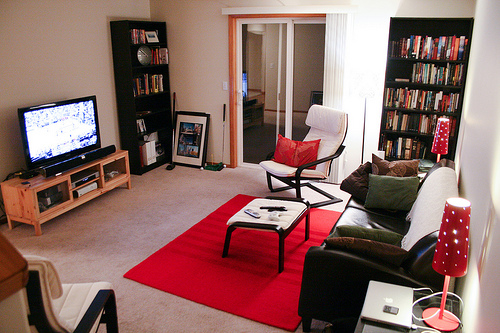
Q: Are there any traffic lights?
A: No, there are no traffic lights.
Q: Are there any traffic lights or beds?
A: No, there are no traffic lights or beds.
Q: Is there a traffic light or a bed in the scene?
A: No, there are no traffic lights or beds.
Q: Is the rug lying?
A: Yes, the rug is lying.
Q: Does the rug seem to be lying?
A: Yes, the rug is lying.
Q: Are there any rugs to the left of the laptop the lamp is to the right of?
A: Yes, there is a rug to the left of the laptop computer.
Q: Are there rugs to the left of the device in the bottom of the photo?
A: Yes, there is a rug to the left of the laptop computer.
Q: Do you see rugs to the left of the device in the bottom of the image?
A: Yes, there is a rug to the left of the laptop computer.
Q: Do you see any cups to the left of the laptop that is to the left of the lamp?
A: No, there is a rug to the left of the laptop.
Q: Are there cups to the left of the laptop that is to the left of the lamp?
A: No, there is a rug to the left of the laptop.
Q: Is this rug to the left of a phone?
A: No, the rug is to the left of the laptop.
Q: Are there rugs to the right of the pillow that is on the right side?
A: No, the rug is to the left of the pillow.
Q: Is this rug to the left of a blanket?
A: No, the rug is to the left of the pillow.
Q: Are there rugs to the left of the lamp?
A: Yes, there is a rug to the left of the lamp.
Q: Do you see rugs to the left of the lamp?
A: Yes, there is a rug to the left of the lamp.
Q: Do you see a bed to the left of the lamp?
A: No, there is a rug to the left of the lamp.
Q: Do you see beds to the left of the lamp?
A: No, there is a rug to the left of the lamp.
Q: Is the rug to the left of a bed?
A: No, the rug is to the left of a lamp.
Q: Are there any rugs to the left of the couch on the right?
A: Yes, there is a rug to the left of the couch.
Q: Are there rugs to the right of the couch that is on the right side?
A: No, the rug is to the left of the couch.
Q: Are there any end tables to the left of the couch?
A: No, there is a rug to the left of the couch.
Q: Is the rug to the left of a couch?
A: Yes, the rug is to the left of a couch.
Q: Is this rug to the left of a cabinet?
A: No, the rug is to the left of a couch.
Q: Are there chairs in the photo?
A: Yes, there is a chair.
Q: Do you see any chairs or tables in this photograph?
A: Yes, there is a chair.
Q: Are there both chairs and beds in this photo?
A: No, there is a chair but no beds.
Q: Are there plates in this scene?
A: No, there are no plates.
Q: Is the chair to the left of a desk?
A: No, the chair is to the left of a pillow.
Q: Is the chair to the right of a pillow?
A: No, the chair is to the left of a pillow.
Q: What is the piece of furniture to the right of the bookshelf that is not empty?
A: The piece of furniture is a chair.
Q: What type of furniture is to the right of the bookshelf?
A: The piece of furniture is a chair.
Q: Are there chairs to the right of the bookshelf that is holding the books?
A: Yes, there is a chair to the right of the bookshelf.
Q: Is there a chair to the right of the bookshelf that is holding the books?
A: Yes, there is a chair to the right of the bookshelf.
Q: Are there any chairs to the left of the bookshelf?
A: No, the chair is to the right of the bookshelf.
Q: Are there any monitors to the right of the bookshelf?
A: No, there is a chair to the right of the bookshelf.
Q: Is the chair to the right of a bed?
A: No, the chair is to the right of the bookshelf.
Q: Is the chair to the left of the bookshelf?
A: No, the chair is to the right of the bookshelf.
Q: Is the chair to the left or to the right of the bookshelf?
A: The chair is to the right of the bookshelf.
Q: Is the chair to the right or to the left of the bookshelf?
A: The chair is to the right of the bookshelf.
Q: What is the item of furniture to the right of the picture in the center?
A: The piece of furniture is a chair.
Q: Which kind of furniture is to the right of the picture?
A: The piece of furniture is a chair.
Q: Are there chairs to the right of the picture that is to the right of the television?
A: Yes, there is a chair to the right of the picture.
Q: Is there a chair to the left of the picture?
A: No, the chair is to the right of the picture.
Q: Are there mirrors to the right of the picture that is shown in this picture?
A: No, there is a chair to the right of the picture.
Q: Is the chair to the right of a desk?
A: No, the chair is to the right of the picture.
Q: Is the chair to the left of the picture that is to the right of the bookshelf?
A: No, the chair is to the right of the picture.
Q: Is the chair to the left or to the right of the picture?
A: The chair is to the right of the picture.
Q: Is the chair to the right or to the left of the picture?
A: The chair is to the right of the picture.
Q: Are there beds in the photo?
A: No, there are no beds.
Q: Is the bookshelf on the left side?
A: Yes, the bookshelf is on the left of the image.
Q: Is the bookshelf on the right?
A: No, the bookshelf is on the left of the image.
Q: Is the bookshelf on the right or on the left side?
A: The bookshelf is on the left of the image.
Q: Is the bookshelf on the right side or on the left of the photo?
A: The bookshelf is on the left of the image.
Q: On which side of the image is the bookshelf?
A: The bookshelf is on the left of the image.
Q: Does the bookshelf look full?
A: Yes, the bookshelf is full.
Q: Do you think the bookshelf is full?
A: Yes, the bookshelf is full.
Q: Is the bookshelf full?
A: Yes, the bookshelf is full.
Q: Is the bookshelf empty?
A: No, the bookshelf is full.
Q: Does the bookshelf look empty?
A: No, the bookshelf is full.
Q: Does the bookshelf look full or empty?
A: The bookshelf is full.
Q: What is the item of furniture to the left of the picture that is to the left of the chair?
A: The piece of furniture is a bookshelf.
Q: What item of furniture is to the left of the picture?
A: The piece of furniture is a bookshelf.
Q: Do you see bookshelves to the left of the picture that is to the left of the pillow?
A: Yes, there is a bookshelf to the left of the picture.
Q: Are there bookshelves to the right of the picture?
A: No, the bookshelf is to the left of the picture.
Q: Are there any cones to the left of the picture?
A: No, there is a bookshelf to the left of the picture.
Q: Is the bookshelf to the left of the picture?
A: Yes, the bookshelf is to the left of the picture.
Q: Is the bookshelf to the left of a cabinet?
A: No, the bookshelf is to the left of the picture.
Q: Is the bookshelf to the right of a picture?
A: No, the bookshelf is to the left of a picture.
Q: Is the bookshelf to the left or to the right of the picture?
A: The bookshelf is to the left of the picture.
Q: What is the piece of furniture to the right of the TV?
A: The piece of furniture is a bookshelf.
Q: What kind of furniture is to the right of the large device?
A: The piece of furniture is a bookshelf.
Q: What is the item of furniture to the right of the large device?
A: The piece of furniture is a bookshelf.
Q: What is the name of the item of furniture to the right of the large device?
A: The piece of furniture is a bookshelf.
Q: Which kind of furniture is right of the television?
A: The piece of furniture is a bookshelf.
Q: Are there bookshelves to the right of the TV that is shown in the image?
A: Yes, there is a bookshelf to the right of the TV.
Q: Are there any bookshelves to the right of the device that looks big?
A: Yes, there is a bookshelf to the right of the TV.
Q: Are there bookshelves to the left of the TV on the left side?
A: No, the bookshelf is to the right of the TV.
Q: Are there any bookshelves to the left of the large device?
A: No, the bookshelf is to the right of the TV.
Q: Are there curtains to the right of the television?
A: No, there is a bookshelf to the right of the television.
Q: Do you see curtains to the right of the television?
A: No, there is a bookshelf to the right of the television.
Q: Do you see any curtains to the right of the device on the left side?
A: No, there is a bookshelf to the right of the television.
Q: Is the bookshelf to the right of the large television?
A: Yes, the bookshelf is to the right of the television.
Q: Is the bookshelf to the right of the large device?
A: Yes, the bookshelf is to the right of the television.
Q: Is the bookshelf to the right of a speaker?
A: No, the bookshelf is to the right of the television.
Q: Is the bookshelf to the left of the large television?
A: No, the bookshelf is to the right of the television.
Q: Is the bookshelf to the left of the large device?
A: No, the bookshelf is to the right of the television.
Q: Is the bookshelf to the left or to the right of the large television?
A: The bookshelf is to the right of the television.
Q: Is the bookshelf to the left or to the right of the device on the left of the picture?
A: The bookshelf is to the right of the television.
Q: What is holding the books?
A: The bookshelf is holding the books.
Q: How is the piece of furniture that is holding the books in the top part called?
A: The piece of furniture is a bookshelf.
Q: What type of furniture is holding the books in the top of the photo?
A: The piece of furniture is a bookshelf.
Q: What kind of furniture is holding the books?
A: The piece of furniture is a bookshelf.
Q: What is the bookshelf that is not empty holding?
A: The bookshelf is holding the books.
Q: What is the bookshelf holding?
A: The bookshelf is holding the books.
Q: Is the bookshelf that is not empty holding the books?
A: Yes, the bookshelf is holding the books.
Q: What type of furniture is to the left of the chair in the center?
A: The piece of furniture is a bookshelf.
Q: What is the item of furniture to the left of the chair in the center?
A: The piece of furniture is a bookshelf.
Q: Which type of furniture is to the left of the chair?
A: The piece of furniture is a bookshelf.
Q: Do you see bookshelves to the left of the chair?
A: Yes, there is a bookshelf to the left of the chair.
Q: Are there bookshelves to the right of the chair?
A: No, the bookshelf is to the left of the chair.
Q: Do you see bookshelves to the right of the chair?
A: No, the bookshelf is to the left of the chair.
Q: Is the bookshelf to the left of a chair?
A: Yes, the bookshelf is to the left of a chair.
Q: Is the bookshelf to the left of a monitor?
A: No, the bookshelf is to the left of a chair.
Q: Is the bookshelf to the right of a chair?
A: No, the bookshelf is to the left of a chair.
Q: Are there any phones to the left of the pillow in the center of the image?
A: No, there is a bookshelf to the left of the pillow.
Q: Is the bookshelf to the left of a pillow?
A: Yes, the bookshelf is to the left of a pillow.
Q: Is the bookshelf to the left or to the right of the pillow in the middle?
A: The bookshelf is to the left of the pillow.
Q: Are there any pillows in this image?
A: Yes, there is a pillow.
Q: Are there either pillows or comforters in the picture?
A: Yes, there is a pillow.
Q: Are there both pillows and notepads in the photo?
A: No, there is a pillow but no notepads.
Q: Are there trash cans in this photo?
A: No, there are no trash cans.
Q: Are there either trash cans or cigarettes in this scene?
A: No, there are no trash cans or cigarettes.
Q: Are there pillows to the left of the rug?
A: No, the pillow is to the right of the rug.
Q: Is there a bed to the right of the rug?
A: No, there is a pillow to the right of the rug.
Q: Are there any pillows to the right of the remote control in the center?
A: Yes, there is a pillow to the right of the remote control.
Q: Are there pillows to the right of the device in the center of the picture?
A: Yes, there is a pillow to the right of the remote control.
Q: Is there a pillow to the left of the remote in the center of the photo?
A: No, the pillow is to the right of the remote control.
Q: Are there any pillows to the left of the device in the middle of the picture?
A: No, the pillow is to the right of the remote control.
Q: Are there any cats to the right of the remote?
A: No, there is a pillow to the right of the remote.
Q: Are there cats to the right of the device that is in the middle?
A: No, there is a pillow to the right of the remote.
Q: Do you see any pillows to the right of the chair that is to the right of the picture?
A: Yes, there is a pillow to the right of the chair.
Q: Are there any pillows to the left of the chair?
A: No, the pillow is to the right of the chair.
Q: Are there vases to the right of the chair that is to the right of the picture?
A: No, there is a pillow to the right of the chair.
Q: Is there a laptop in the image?
A: Yes, there is a laptop.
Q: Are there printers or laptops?
A: Yes, there is a laptop.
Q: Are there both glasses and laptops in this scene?
A: No, there is a laptop but no glasses.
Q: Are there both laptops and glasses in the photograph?
A: No, there is a laptop but no glasses.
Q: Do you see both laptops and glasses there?
A: No, there is a laptop but no glasses.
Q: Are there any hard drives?
A: No, there are no hard drives.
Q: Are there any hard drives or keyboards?
A: No, there are no hard drives or keyboards.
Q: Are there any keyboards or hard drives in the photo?
A: No, there are no hard drives or keyboards.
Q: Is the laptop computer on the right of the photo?
A: Yes, the laptop computer is on the right of the image.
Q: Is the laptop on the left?
A: No, the laptop is on the right of the image.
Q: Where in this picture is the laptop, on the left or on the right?
A: The laptop is on the right of the image.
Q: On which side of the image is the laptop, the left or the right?
A: The laptop is on the right of the image.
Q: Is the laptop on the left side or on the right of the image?
A: The laptop is on the right of the image.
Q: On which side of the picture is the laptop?
A: The laptop is on the right of the image.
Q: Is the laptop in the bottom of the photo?
A: Yes, the laptop is in the bottom of the image.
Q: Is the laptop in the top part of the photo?
A: No, the laptop is in the bottom of the image.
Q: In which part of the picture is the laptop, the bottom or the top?
A: The laptop is in the bottom of the image.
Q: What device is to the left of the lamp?
A: The device is a laptop.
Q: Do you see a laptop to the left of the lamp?
A: Yes, there is a laptop to the left of the lamp.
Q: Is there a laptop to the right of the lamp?
A: No, the laptop is to the left of the lamp.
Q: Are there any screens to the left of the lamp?
A: No, there is a laptop to the left of the lamp.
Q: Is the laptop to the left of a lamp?
A: Yes, the laptop is to the left of a lamp.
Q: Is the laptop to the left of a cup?
A: No, the laptop is to the left of a lamp.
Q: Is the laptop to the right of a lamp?
A: No, the laptop is to the left of a lamp.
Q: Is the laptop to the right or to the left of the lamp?
A: The laptop is to the left of the lamp.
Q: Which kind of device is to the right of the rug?
A: The device is a laptop.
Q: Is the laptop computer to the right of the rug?
A: Yes, the laptop computer is to the right of the rug.